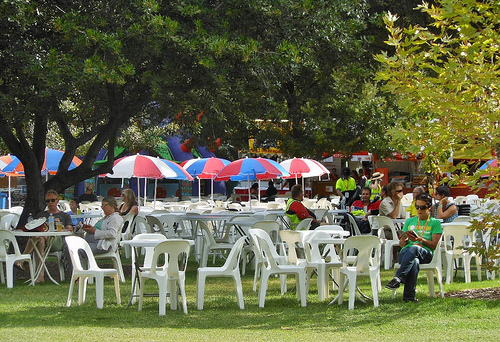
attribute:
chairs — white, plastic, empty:
[62, 231, 125, 312]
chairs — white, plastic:
[134, 234, 193, 320]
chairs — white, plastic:
[193, 230, 252, 312]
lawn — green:
[2, 196, 499, 339]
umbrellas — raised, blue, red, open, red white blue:
[216, 153, 291, 188]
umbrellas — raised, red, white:
[95, 155, 195, 185]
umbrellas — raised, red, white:
[276, 157, 330, 182]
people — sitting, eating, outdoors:
[377, 179, 412, 269]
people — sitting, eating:
[430, 187, 458, 247]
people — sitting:
[62, 195, 123, 285]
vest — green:
[286, 195, 306, 232]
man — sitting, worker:
[285, 187, 349, 267]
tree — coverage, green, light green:
[361, 1, 500, 301]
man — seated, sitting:
[385, 192, 444, 311]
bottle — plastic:
[47, 213, 58, 232]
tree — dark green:
[1, 1, 307, 268]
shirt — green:
[397, 213, 442, 259]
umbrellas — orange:
[1, 140, 94, 185]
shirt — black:
[79, 192, 98, 205]